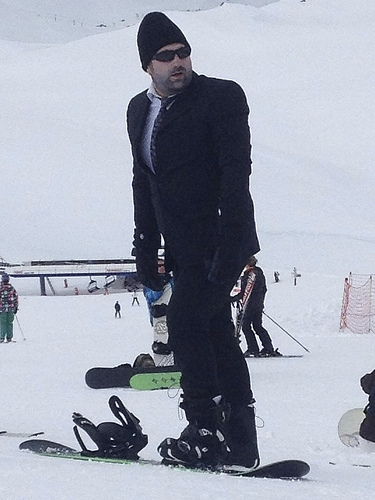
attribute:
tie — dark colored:
[151, 98, 165, 174]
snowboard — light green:
[82, 364, 184, 389]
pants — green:
[0, 305, 20, 338]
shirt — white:
[141, 79, 180, 170]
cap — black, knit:
[137, 10, 190, 69]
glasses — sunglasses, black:
[126, 12, 261, 471]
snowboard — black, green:
[21, 423, 323, 485]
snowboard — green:
[18, 436, 311, 480]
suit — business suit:
[126, 71, 261, 392]